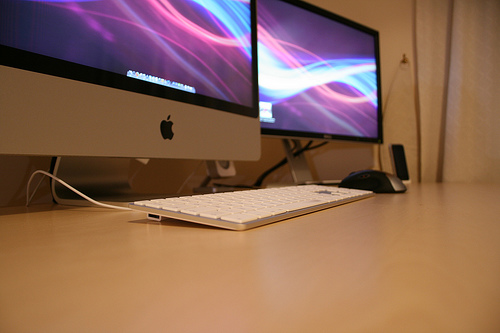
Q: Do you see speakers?
A: Yes, there is a speaker.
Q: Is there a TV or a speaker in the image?
A: Yes, there is a speaker.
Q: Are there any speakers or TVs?
A: Yes, there is a speaker.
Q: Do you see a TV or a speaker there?
A: Yes, there is a speaker.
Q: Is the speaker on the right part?
A: Yes, the speaker is on the right of the image.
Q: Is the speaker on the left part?
A: No, the speaker is on the right of the image.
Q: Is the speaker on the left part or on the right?
A: The speaker is on the right of the image.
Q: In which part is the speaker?
A: The speaker is on the right of the image.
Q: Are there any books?
A: No, there are no books.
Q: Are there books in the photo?
A: No, there are no books.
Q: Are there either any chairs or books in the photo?
A: No, there are no books or chairs.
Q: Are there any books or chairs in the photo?
A: No, there are no books or chairs.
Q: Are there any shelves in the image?
A: No, there are no shelves.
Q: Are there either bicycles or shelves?
A: No, there are no shelves or bicycles.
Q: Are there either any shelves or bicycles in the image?
A: No, there are no shelves or bicycles.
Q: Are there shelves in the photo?
A: No, there are no shelves.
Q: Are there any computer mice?
A: Yes, there is a computer mouse.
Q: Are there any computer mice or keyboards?
A: Yes, there is a computer mouse.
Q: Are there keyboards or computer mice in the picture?
A: Yes, there is a computer mouse.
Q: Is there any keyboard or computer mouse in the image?
A: Yes, there is a computer mouse.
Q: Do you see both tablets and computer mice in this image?
A: No, there is a computer mouse but no tablets.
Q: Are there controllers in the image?
A: No, there are no controllers.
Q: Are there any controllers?
A: No, there are no controllers.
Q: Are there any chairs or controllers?
A: No, there are no controllers or chairs.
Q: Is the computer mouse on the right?
A: Yes, the computer mouse is on the right of the image.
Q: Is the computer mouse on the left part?
A: No, the computer mouse is on the right of the image.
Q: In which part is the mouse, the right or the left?
A: The mouse is on the right of the image.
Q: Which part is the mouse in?
A: The mouse is on the right of the image.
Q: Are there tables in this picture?
A: Yes, there is a table.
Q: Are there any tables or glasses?
A: Yes, there is a table.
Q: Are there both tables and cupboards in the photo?
A: No, there is a table but no cupboards.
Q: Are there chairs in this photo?
A: No, there are no chairs.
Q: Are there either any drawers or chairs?
A: No, there are no chairs or drawers.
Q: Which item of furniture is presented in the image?
A: The piece of furniture is a table.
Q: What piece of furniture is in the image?
A: The piece of furniture is a table.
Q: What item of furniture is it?
A: The piece of furniture is a table.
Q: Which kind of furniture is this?
A: That is a table.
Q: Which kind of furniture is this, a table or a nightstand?
A: That is a table.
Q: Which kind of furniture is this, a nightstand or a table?
A: That is a table.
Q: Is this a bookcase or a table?
A: This is a table.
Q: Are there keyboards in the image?
A: Yes, there is a keyboard.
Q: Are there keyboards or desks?
A: Yes, there is a keyboard.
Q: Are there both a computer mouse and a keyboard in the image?
A: Yes, there are both a keyboard and a computer mouse.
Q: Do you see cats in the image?
A: No, there are no cats.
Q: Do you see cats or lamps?
A: No, there are no cats or lamps.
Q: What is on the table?
A: The keyboard is on the table.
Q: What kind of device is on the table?
A: The device is a keyboard.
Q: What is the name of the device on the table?
A: The device is a keyboard.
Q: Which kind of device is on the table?
A: The device is a keyboard.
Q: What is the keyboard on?
A: The keyboard is on the table.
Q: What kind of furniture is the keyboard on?
A: The keyboard is on the table.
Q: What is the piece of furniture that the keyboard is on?
A: The piece of furniture is a table.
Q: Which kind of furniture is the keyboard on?
A: The keyboard is on the table.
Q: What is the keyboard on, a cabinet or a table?
A: The keyboard is on a table.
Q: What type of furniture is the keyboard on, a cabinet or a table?
A: The keyboard is on a table.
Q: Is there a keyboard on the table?
A: Yes, there is a keyboard on the table.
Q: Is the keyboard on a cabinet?
A: No, the keyboard is on the table.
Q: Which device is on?
A: The device is a monitor.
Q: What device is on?
A: The device is a monitor.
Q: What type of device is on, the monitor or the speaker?
A: The monitor is on.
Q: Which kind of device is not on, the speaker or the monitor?
A: The speaker is not on.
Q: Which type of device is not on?
A: The device is a speaker.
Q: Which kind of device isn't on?
A: The device is a speaker.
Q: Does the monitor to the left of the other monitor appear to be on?
A: Yes, the monitor is on.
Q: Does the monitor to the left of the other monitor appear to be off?
A: No, the monitor is on.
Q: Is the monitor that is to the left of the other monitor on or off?
A: The monitor is on.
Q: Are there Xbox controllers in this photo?
A: No, there are no Xbox controllers.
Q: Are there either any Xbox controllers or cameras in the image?
A: No, there are no Xbox controllers or cameras.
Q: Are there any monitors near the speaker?
A: Yes, there is a monitor near the speaker.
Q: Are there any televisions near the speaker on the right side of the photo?
A: No, there is a monitor near the speaker.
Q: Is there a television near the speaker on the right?
A: No, there is a monitor near the speaker.